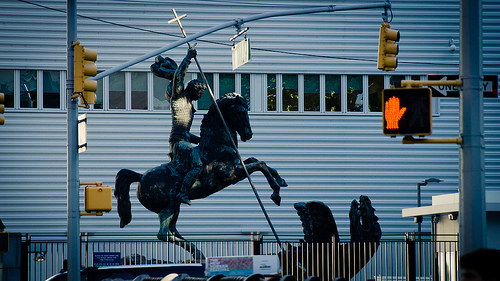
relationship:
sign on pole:
[376, 79, 441, 144] [445, 54, 487, 174]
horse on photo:
[64, 89, 299, 252] [3, 4, 490, 271]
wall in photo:
[294, 155, 394, 196] [3, 4, 490, 271]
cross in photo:
[163, 2, 193, 40] [3, 4, 490, 271]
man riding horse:
[141, 36, 208, 209] [112, 87, 295, 262]